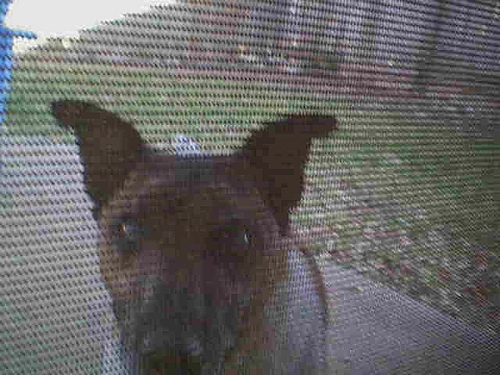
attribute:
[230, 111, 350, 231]
ear — black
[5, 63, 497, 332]
grass — green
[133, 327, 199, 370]
nose — black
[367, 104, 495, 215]
grass — green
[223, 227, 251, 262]
left eye — black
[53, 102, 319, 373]
dog — round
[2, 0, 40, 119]
object — blue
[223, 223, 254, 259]
eye — round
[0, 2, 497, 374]
fence — brown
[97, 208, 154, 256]
eye — black